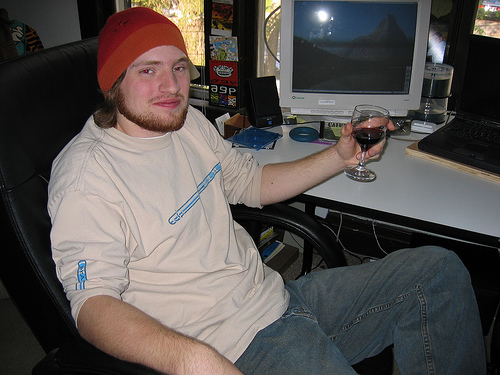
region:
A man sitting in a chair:
[71, 18, 457, 348]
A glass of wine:
[331, 93, 411, 207]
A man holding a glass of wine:
[64, 9, 416, 213]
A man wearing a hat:
[85, 11, 203, 139]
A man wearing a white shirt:
[77, 18, 257, 332]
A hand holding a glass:
[329, 101, 404, 214]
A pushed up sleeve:
[215, 109, 298, 225]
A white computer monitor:
[252, 17, 443, 140]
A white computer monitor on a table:
[262, 10, 433, 142]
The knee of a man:
[368, 240, 476, 343]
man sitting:
[62, 10, 446, 367]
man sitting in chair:
[79, 8, 454, 360]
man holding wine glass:
[76, 10, 453, 362]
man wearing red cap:
[62, 9, 263, 150]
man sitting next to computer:
[75, 8, 465, 360]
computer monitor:
[261, 6, 446, 131]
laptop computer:
[417, 14, 498, 196]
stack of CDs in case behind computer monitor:
[400, 40, 462, 150]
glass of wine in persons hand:
[330, 85, 405, 215]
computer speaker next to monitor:
[236, 66, 292, 146]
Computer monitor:
[265, 2, 450, 126]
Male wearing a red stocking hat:
[69, 1, 249, 276]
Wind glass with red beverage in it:
[337, 91, 395, 186]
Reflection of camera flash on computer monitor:
[306, 5, 346, 42]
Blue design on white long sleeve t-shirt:
[159, 140, 237, 229]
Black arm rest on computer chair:
[296, 204, 349, 272]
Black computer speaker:
[242, 75, 286, 135]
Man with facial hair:
[111, 38, 205, 138]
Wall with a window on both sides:
[185, 1, 282, 69]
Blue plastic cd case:
[228, 126, 283, 153]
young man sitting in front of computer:
[42, 23, 470, 347]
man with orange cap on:
[75, 1, 200, 148]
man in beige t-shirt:
[38, 84, 291, 353]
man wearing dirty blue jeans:
[110, 254, 479, 362]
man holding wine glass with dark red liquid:
[237, 94, 392, 241]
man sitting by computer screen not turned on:
[119, 0, 441, 236]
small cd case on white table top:
[226, 116, 283, 152]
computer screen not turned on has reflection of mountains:
[255, 2, 459, 146]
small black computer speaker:
[237, 73, 284, 133]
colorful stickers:
[204, 1, 252, 120]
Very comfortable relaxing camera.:
[62, 5, 264, 367]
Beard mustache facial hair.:
[82, 7, 202, 150]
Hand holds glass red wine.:
[267, 104, 428, 201]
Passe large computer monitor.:
[270, 0, 427, 140]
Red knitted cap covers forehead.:
[87, 3, 191, 81]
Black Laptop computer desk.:
[428, 32, 498, 172]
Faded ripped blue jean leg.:
[290, 253, 495, 374]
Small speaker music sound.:
[240, 63, 287, 128]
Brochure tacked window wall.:
[205, 2, 244, 107]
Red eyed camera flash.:
[133, 55, 193, 77]